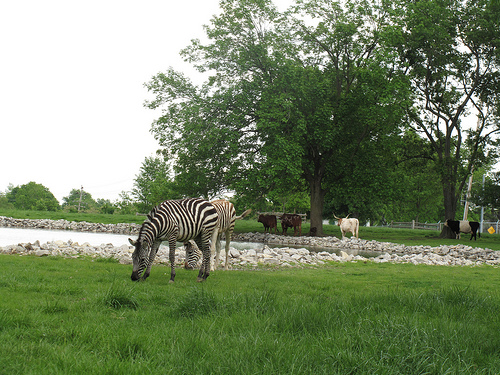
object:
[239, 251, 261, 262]
rocks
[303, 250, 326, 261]
rocks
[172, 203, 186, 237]
stripes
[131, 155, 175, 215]
tree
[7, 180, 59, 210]
tree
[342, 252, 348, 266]
rocks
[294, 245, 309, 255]
rocks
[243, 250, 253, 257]
rocks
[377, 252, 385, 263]
rocks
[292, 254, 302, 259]
rocks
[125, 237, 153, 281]
head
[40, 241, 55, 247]
rocks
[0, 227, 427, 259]
pond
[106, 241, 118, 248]
rocks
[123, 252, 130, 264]
rocks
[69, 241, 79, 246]
rocks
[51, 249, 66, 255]
rocks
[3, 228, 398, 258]
water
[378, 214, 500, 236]
fence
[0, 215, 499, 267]
piles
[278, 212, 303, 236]
cow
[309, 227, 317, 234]
black spot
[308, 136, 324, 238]
tree trunk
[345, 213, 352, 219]
horns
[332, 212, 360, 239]
cattle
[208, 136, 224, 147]
leaf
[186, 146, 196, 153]
leaf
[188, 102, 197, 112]
leaf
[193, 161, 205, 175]
leaf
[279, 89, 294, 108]
leaf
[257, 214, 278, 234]
animals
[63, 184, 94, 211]
trees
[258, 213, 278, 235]
cow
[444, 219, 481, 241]
cow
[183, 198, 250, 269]
zebra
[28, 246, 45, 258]
rocks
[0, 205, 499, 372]
field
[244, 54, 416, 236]
tree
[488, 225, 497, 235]
sign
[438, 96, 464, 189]
branches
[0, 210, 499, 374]
ground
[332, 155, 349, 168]
leaves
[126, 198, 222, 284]
zebra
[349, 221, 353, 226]
patch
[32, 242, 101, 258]
rocks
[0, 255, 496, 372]
grass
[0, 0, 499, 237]
background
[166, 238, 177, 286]
leg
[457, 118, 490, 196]
branch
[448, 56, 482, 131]
branch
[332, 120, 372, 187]
branch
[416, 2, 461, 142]
branch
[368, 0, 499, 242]
tree